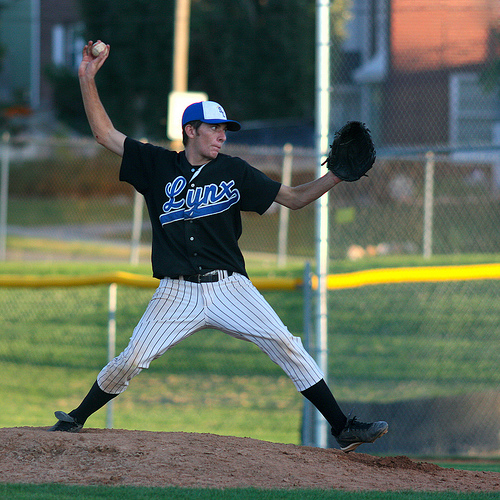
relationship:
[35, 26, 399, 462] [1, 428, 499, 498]
game in baseball field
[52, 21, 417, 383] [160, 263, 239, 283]
baseball pitcher has belt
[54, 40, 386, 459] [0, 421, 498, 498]
baseball pitcher on dirt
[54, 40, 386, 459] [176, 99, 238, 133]
baseball pitcher has hat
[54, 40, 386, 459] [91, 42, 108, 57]
baseball pitcher trows baseball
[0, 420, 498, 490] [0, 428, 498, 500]
dirt in baseball field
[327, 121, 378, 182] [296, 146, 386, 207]
baseball glove in hands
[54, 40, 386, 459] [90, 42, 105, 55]
baseball pitcher with baseball